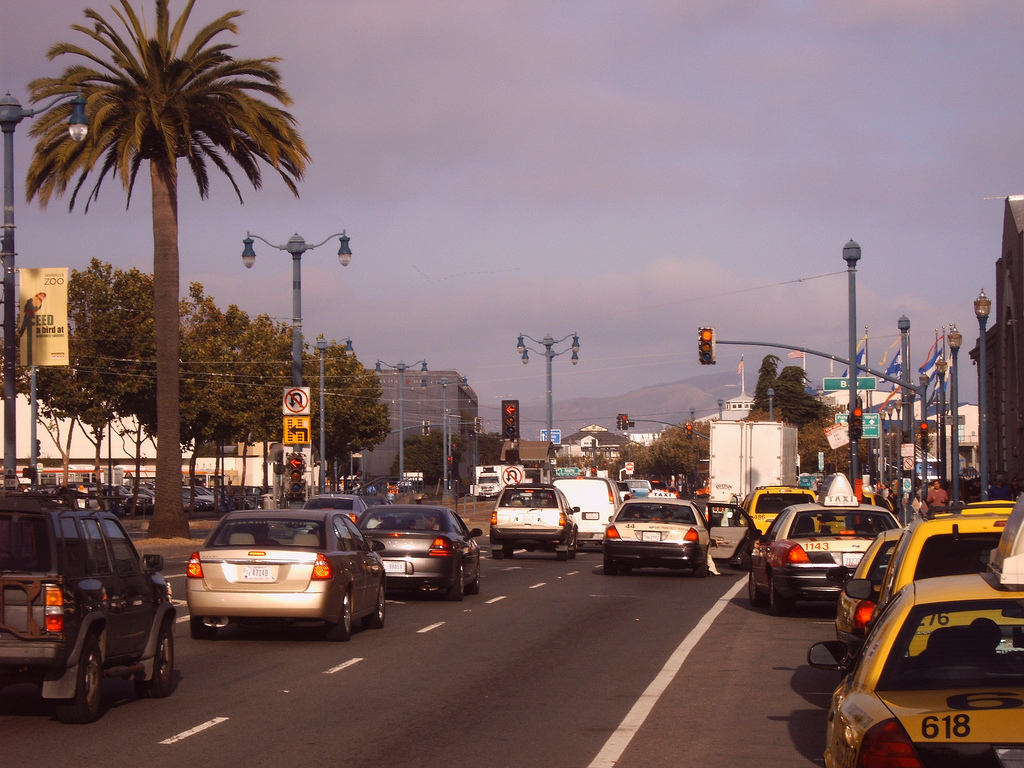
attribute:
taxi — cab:
[828, 549, 1023, 766]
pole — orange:
[721, 333, 903, 388]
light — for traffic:
[688, 322, 714, 366]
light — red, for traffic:
[498, 392, 529, 447]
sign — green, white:
[546, 454, 609, 487]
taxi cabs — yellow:
[719, 476, 1020, 764]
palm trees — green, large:
[1, 1, 405, 578]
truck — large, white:
[699, 418, 806, 516]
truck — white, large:
[461, 455, 554, 508]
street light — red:
[489, 381, 528, 474]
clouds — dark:
[6, 14, 1020, 462]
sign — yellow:
[263, 418, 322, 473]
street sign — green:
[798, 355, 894, 446]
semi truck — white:
[703, 405, 812, 537]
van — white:
[550, 467, 620, 556]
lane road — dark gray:
[1, 545, 717, 759]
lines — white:
[152, 565, 751, 760]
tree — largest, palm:
[72, 26, 228, 186]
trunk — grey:
[126, 191, 224, 583]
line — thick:
[599, 605, 701, 729]